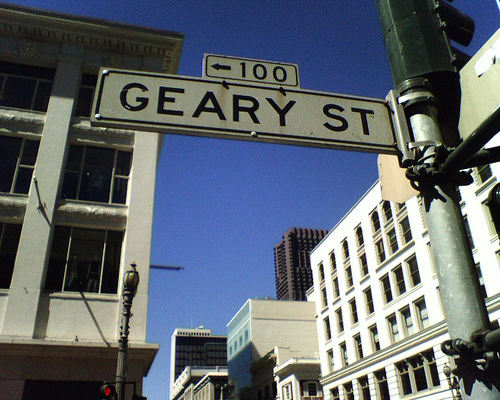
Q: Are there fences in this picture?
A: No, there are no fences.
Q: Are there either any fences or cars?
A: No, there are no fences or cars.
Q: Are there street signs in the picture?
A: Yes, there is a street sign.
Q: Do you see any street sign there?
A: Yes, there is a street sign.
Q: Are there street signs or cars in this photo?
A: Yes, there is a street sign.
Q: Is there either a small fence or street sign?
A: Yes, there is a small street sign.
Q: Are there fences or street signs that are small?
A: Yes, the street sign is small.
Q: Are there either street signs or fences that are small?
A: Yes, the street sign is small.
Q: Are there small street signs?
A: Yes, there is a small street sign.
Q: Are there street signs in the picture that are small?
A: Yes, there is a street sign that is small.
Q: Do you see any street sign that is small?
A: Yes, there is a street sign that is small.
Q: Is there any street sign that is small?
A: Yes, there is a street sign that is small.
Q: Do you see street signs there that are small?
A: Yes, there is a street sign that is small.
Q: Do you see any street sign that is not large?
A: Yes, there is a small street sign.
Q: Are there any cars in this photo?
A: No, there are no cars.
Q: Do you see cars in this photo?
A: No, there are no cars.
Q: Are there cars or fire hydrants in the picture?
A: No, there are no cars or fire hydrants.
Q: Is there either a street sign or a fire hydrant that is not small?
A: No, there is a street sign but it is small.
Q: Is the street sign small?
A: Yes, the street sign is small.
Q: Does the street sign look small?
A: Yes, the street sign is small.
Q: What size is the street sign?
A: The street sign is small.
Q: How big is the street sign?
A: The street sign is small.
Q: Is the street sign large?
A: No, the street sign is small.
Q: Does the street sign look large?
A: No, the street sign is small.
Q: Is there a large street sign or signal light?
A: No, there is a street sign but it is small.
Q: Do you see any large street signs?
A: No, there is a street sign but it is small.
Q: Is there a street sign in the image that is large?
A: No, there is a street sign but it is small.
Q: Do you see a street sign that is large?
A: No, there is a street sign but it is small.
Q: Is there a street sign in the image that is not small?
A: No, there is a street sign but it is small.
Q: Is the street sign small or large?
A: The street sign is small.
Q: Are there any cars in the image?
A: No, there are no cars.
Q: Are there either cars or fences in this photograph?
A: No, there are no cars or fences.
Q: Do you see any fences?
A: No, there are no fences.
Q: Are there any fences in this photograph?
A: No, there are no fences.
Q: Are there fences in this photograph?
A: No, there are no fences.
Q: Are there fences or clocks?
A: No, there are no fences or clocks.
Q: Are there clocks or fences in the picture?
A: No, there are no fences or clocks.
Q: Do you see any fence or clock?
A: No, there are no fences or clocks.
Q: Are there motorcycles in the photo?
A: No, there are no motorcycles.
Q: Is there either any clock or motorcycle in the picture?
A: No, there are no motorcycles or clocks.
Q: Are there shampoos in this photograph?
A: No, there are no shampoos.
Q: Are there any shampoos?
A: No, there are no shampoos.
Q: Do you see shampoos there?
A: No, there are no shampoos.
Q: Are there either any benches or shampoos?
A: No, there are no shampoos or benches.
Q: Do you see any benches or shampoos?
A: No, there are no shampoos or benches.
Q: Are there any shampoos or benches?
A: No, there are no shampoos or benches.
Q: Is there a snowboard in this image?
A: No, there are no snowboards.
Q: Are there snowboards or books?
A: No, there are no snowboards or books.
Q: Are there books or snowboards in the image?
A: No, there are no snowboards or books.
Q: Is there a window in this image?
A: Yes, there is a window.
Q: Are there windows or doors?
A: Yes, there is a window.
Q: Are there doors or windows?
A: Yes, there is a window.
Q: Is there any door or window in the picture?
A: Yes, there is a window.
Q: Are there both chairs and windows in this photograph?
A: No, there is a window but no chairs.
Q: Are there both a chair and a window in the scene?
A: No, there is a window but no chairs.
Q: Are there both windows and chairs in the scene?
A: No, there is a window but no chairs.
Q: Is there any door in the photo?
A: No, there are no doors.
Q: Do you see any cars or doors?
A: No, there are no doors or cars.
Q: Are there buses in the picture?
A: No, there are no buses.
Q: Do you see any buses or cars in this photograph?
A: No, there are no buses or cars.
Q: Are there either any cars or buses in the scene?
A: No, there are no buses or cars.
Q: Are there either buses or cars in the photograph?
A: No, there are no buses or cars.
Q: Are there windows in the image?
A: Yes, there are windows.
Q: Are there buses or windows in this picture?
A: Yes, there are windows.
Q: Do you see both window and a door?
A: No, there are windows but no doors.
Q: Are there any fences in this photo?
A: No, there are no fences.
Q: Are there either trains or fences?
A: No, there are no fences or trains.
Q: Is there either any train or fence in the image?
A: No, there are no fences or trains.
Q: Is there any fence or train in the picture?
A: No, there are no fences or trains.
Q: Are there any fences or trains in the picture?
A: No, there are no fences or trains.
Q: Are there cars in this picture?
A: No, there are no cars.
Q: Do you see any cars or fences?
A: No, there are no cars or fences.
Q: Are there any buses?
A: No, there are no buses.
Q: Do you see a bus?
A: No, there are no buses.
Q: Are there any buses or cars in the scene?
A: No, there are no buses or cars.